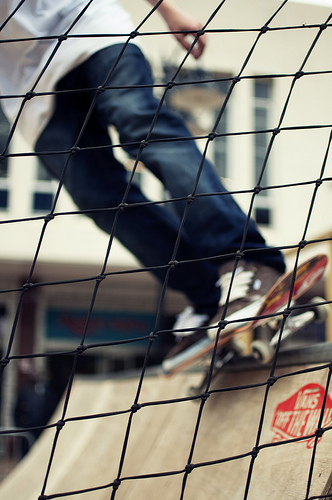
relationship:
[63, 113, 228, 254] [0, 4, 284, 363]
legs of person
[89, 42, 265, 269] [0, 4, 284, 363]
leg of a person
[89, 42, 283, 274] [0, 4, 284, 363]
leg of a person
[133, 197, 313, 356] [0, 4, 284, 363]
feet of a person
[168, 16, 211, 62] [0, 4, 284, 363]
finger of a person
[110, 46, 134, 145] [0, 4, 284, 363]
thigh of a person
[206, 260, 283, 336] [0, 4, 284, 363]
sneaker of a person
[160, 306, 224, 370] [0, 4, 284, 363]
sneaker of a person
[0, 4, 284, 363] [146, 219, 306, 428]
person on skateboard